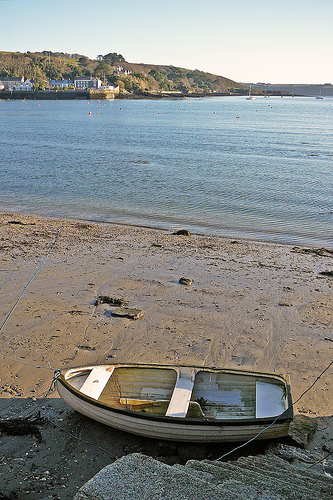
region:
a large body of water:
[1, 94, 331, 235]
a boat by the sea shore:
[54, 357, 301, 445]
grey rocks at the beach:
[59, 445, 332, 498]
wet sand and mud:
[0, 210, 331, 415]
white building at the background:
[1, 76, 34, 91]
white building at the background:
[44, 76, 76, 93]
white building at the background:
[117, 63, 133, 74]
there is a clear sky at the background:
[2, 0, 330, 86]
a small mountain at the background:
[0, 50, 244, 90]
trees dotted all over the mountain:
[4, 50, 250, 92]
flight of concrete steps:
[66, 441, 328, 499]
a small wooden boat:
[44, 354, 307, 445]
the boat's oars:
[117, 392, 216, 417]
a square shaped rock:
[106, 301, 146, 323]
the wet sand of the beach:
[8, 215, 330, 436]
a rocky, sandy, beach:
[0, 211, 329, 498]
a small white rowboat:
[47, 354, 300, 450]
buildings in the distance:
[3, 66, 146, 106]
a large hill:
[1, 45, 310, 105]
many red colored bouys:
[12, 97, 304, 124]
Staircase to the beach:
[180, 462, 332, 499]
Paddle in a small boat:
[117, 395, 173, 405]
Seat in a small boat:
[166, 360, 197, 427]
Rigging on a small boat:
[49, 367, 67, 381]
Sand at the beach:
[38, 313, 126, 343]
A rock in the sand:
[106, 305, 146, 320]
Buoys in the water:
[84, 105, 104, 123]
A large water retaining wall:
[31, 89, 114, 100]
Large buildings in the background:
[75, 72, 104, 91]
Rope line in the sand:
[8, 243, 59, 326]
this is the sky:
[182, 6, 311, 23]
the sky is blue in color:
[205, 1, 293, 12]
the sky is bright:
[218, 42, 315, 71]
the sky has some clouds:
[220, 45, 332, 71]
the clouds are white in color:
[210, 46, 331, 83]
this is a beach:
[55, 205, 297, 307]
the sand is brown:
[39, 268, 236, 326]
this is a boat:
[47, 369, 293, 444]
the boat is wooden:
[139, 393, 259, 416]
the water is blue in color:
[152, 113, 263, 190]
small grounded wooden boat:
[54, 361, 292, 441]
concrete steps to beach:
[75, 451, 332, 499]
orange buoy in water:
[87, 109, 92, 115]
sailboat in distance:
[313, 87, 322, 102]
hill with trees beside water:
[3, 50, 252, 97]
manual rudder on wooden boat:
[119, 394, 206, 414]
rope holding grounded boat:
[3, 352, 60, 417]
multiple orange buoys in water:
[76, 99, 272, 121]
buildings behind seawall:
[2, 74, 102, 91]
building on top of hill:
[96, 52, 103, 60]